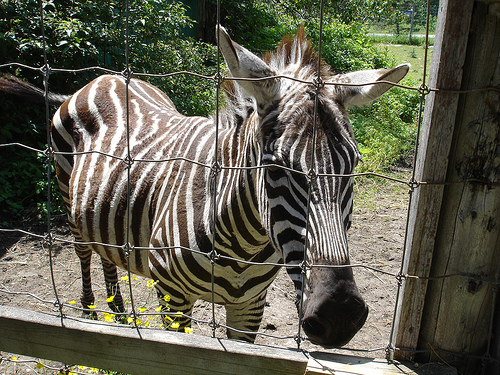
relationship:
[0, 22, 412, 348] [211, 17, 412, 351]
animal has head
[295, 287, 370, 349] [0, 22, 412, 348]
nose of animal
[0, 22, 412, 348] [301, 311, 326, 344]
animal has nostril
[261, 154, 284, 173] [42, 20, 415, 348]
eye of animal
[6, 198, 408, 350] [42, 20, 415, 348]
dirt under animal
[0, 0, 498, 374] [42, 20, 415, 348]
fence in front of animal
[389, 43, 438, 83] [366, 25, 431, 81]
grass on ground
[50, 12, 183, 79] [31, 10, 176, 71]
leaves on trees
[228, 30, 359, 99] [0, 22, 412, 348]
hair on animal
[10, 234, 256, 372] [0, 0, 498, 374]
flowers behind fence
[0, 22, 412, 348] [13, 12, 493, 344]
animal looking at fence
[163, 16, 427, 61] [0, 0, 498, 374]
foliage behind fence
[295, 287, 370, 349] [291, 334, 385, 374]
nose making a shadow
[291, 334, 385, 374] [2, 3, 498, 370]
shadow on fence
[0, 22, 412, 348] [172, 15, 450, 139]
animal has ears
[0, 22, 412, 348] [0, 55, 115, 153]
animal swhing its tail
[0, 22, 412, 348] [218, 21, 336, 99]
animal has hair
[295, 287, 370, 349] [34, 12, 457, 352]
nose through fence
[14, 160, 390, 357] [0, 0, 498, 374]
grass near fence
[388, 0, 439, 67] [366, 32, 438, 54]
sign post near ground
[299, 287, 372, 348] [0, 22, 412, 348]
nose belonging to animal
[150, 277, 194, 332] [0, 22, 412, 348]
leg belonging to animal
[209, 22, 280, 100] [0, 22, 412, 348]
ear belonging to animal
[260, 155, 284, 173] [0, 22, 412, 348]
eye belonging to animal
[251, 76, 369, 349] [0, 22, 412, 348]
head belonging to animal